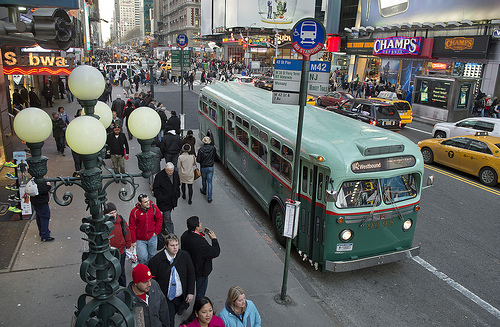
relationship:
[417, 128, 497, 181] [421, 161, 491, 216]
cab on street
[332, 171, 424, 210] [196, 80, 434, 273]
window on bus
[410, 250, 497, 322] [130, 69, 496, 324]
line on road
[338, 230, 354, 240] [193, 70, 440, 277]
head light on bus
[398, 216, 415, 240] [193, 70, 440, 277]
light on bus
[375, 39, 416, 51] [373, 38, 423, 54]
letters on sign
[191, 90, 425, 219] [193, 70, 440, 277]
red strip on bus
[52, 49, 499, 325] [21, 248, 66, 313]
people on sidewalk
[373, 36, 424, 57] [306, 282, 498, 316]
sign across street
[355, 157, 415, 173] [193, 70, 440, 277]
sign on bus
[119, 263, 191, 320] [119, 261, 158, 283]
man wearing hat